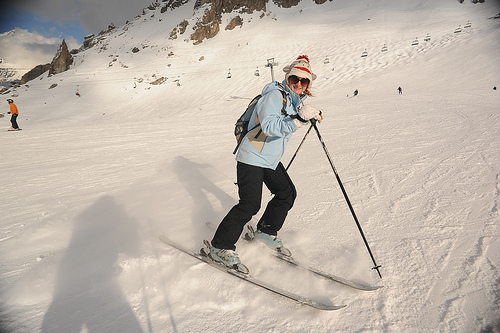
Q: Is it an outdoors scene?
A: Yes, it is outdoors.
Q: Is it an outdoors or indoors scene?
A: It is outdoors.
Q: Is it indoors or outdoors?
A: It is outdoors.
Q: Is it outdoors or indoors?
A: It is outdoors.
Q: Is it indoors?
A: No, it is outdoors.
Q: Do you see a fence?
A: No, there are no fences.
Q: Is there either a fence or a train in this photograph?
A: No, there are no fences or trains.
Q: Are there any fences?
A: No, there are no fences.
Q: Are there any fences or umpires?
A: No, there are no fences or umpires.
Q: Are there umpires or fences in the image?
A: No, there are no fences or umpires.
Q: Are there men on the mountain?
A: Yes, there is a man on the mountain.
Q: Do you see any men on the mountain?
A: Yes, there is a man on the mountain.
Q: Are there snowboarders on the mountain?
A: No, there is a man on the mountain.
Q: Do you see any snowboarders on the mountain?
A: No, there is a man on the mountain.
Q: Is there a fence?
A: No, there are no fences.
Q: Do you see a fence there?
A: No, there are no fences.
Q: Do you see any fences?
A: No, there are no fences.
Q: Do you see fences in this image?
A: No, there are no fences.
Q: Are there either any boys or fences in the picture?
A: No, there are no fences or boys.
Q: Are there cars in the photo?
A: No, there are no cars.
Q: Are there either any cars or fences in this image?
A: No, there are no cars or fences.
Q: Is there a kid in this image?
A: No, there are no children.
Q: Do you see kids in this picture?
A: No, there are no kids.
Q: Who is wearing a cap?
A: The man is wearing a cap.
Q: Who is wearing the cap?
A: The man is wearing a cap.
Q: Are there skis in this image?
A: Yes, there are skis.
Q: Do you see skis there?
A: Yes, there are skis.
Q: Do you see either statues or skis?
A: Yes, there are skis.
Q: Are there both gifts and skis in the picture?
A: No, there are skis but no gifts.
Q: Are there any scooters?
A: No, there are no scooters.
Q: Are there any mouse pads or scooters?
A: No, there are no scooters or mouse pads.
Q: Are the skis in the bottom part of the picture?
A: Yes, the skis are in the bottom of the image.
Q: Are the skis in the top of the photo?
A: No, the skis are in the bottom of the image.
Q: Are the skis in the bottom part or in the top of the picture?
A: The skis are in the bottom of the image.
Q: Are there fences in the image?
A: No, there are no fences.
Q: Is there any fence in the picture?
A: No, there are no fences.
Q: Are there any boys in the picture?
A: No, there are no boys.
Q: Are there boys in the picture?
A: No, there are no boys.